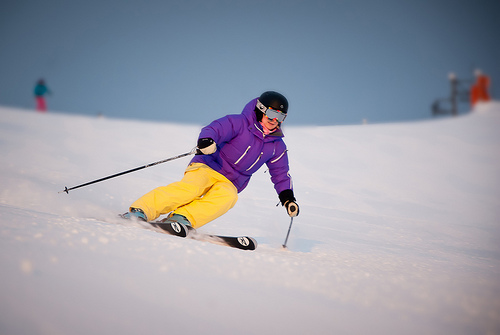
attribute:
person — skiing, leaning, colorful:
[148, 81, 305, 242]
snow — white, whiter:
[318, 152, 483, 311]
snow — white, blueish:
[6, 131, 60, 324]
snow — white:
[72, 254, 370, 334]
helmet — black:
[250, 90, 292, 116]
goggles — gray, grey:
[252, 104, 287, 125]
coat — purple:
[199, 114, 299, 189]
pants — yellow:
[134, 153, 238, 237]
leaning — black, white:
[194, 121, 308, 245]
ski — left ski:
[172, 221, 261, 248]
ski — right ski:
[120, 210, 186, 243]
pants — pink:
[33, 93, 48, 110]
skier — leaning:
[70, 104, 312, 231]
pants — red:
[469, 82, 489, 105]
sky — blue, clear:
[7, 2, 476, 73]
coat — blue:
[33, 84, 53, 95]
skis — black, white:
[110, 203, 273, 261]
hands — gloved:
[193, 141, 299, 217]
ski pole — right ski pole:
[60, 145, 200, 194]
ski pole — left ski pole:
[282, 216, 296, 247]